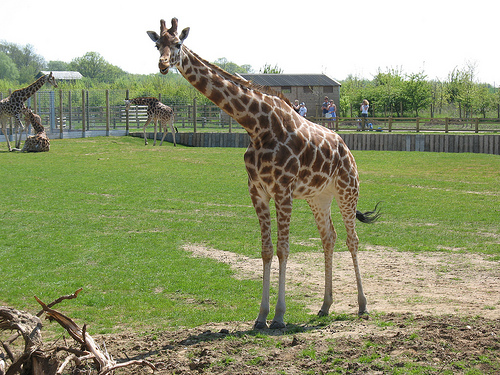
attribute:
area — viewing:
[1, 116, 451, 359]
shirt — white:
[355, 97, 374, 112]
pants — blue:
[354, 109, 371, 124]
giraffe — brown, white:
[145, 19, 376, 327]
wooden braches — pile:
[370, 105, 454, 139]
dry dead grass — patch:
[306, 244, 426, 306]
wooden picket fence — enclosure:
[9, 88, 189, 144]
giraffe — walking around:
[117, 6, 370, 320]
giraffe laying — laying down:
[7, 97, 61, 166]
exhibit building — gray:
[212, 61, 349, 142]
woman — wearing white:
[353, 92, 381, 122]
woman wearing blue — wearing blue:
[321, 101, 346, 132]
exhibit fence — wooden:
[365, 91, 499, 140]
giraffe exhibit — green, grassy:
[4, 4, 410, 351]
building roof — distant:
[228, 61, 343, 95]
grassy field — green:
[28, 160, 213, 244]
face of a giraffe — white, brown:
[154, 34, 189, 72]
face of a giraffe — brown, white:
[48, 72, 65, 95]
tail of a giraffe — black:
[353, 208, 392, 229]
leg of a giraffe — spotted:
[136, 118, 162, 164]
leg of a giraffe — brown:
[263, 196, 314, 359]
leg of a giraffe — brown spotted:
[342, 206, 386, 311]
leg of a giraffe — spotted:
[306, 194, 350, 322]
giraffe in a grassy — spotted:
[53, 184, 172, 274]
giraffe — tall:
[117, 84, 196, 162]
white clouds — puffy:
[256, 6, 344, 49]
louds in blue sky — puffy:
[53, 1, 139, 62]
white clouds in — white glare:
[219, 6, 332, 48]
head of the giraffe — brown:
[117, 97, 139, 116]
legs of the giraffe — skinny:
[241, 178, 314, 337]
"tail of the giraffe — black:
[166, 114, 197, 146]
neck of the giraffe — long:
[180, 50, 266, 141]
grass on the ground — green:
[349, 233, 478, 326]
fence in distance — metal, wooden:
[331, 95, 498, 150]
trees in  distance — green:
[349, 66, 487, 122]